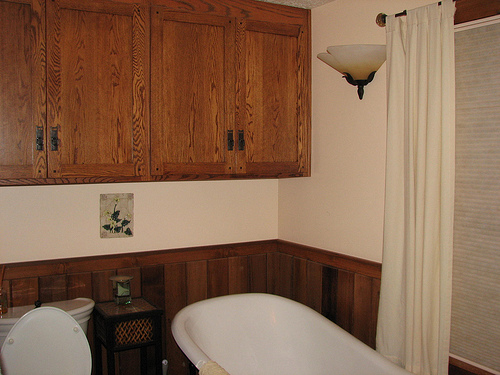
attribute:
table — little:
[91, 304, 165, 368]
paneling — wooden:
[34, 262, 61, 299]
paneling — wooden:
[137, 257, 164, 314]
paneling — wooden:
[162, 255, 187, 316]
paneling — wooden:
[182, 250, 213, 302]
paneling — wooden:
[206, 254, 259, 286]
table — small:
[101, 277, 168, 354]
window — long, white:
[387, 10, 498, 373]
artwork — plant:
[97, 189, 138, 240]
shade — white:
[449, 15, 498, 373]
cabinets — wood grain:
[0, 0, 312, 187]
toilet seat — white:
[12, 317, 81, 368]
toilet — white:
[2, 295, 97, 373]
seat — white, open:
[2, 306, 93, 371]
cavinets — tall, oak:
[1, 7, 309, 178]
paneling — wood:
[2, 236, 384, 289]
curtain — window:
[377, 4, 462, 374]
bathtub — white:
[148, 265, 412, 374]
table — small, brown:
[93, 299, 165, 354]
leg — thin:
[93, 345, 103, 370]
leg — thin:
[102, 348, 120, 371]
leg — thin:
[138, 347, 153, 374]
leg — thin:
[146, 342, 163, 372]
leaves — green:
[118, 215, 133, 236]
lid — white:
[20, 298, 73, 339]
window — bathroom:
[395, 48, 485, 363]